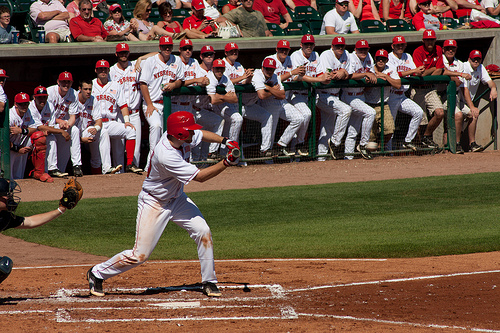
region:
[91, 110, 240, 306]
a batter getting ready to bunt the ball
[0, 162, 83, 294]
a catcher getting ready to grab the ball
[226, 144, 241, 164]
the baseball bat the batter is holding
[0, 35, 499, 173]
a line of players standing in the dugout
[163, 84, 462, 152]
the fence at the edge of the dugout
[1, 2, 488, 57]
the audience watching the game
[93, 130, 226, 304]
the uniform the man is wearing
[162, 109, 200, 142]
the helmet that the batter is wearing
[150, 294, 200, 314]
the home plate of the baseball field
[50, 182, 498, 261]
the green grass on the side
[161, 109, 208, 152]
Man is wearing red helmet.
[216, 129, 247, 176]
Man is wearing gloves.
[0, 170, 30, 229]
Catcher is wearing face guard.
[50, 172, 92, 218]
Catcher is wearing baseball mitt.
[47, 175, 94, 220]
Baseball mitt is leather.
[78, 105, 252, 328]
Man is standing on dirt.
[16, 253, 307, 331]
Dirt has chalk lines.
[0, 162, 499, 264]
Grassy area is green.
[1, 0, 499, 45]
Spectator sitting in bleachers.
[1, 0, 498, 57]
Spectators are on the sidelines.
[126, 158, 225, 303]
the attire is white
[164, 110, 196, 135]
the helmet is red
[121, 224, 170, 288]
the pants have sand on it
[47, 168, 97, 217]
the gloves are black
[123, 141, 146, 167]
the socks are red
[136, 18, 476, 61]
the hats are red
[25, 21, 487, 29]
there are spectators watching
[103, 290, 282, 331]
the lines are white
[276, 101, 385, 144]
the pants are white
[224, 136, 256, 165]
the gloves are white and red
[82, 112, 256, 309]
a baseball player up to bat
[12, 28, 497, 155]
a baseball team in the dugout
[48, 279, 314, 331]
two outlined batter's boxes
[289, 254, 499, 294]
the 3rd base line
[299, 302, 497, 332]
the first base line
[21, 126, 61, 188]
a catchers leg guards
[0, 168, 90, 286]
the opponent team's catcher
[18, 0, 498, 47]
baseball fans in the stands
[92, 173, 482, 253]
a patch of green grass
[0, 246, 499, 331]
dirt on a baseball field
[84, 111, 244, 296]
a batter squaring to bunt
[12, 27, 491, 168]
a dugout full of interested teammates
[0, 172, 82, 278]
a catcher ready to catch the ball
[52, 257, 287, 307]
a batter legally in the batter's box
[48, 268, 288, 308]
a clearly defined batter's box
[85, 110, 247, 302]
player in a red batting helmet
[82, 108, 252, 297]
player in a red helmet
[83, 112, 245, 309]
batter in short sleeve jersey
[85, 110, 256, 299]
batter in short sleeve shirt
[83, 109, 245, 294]
batter in white jersey